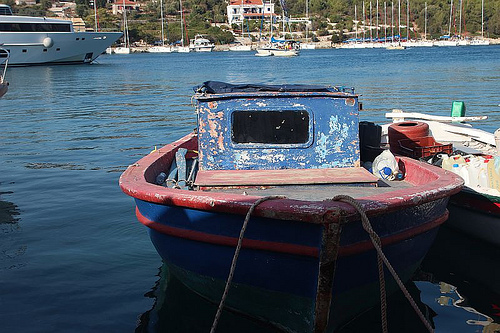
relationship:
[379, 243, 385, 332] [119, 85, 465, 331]
rope on boat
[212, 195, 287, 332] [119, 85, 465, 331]
rope on left side of boat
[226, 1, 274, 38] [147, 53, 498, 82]
house on lake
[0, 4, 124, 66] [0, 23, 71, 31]
yacht has black windows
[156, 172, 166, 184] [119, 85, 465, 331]
bottle on boat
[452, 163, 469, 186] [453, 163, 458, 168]
bottle with blue cap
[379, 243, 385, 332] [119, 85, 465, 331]
rope hanging off boat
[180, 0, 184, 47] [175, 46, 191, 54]
mast on boat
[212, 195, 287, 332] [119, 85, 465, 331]
rope hanging over boat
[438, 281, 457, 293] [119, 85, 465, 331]
sludge near boat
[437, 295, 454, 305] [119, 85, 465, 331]
sludge near boat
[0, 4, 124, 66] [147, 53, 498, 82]
yacht on lake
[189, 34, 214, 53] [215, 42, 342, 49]
boat near shore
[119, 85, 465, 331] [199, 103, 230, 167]
boat has peeling paint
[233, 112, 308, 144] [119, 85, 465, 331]
window on boat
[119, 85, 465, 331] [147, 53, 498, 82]
boat on lake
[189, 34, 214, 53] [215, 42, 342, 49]
boat anchored at shore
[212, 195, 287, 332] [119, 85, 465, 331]
rope attached to boat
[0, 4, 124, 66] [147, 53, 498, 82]
yacht cruising lake